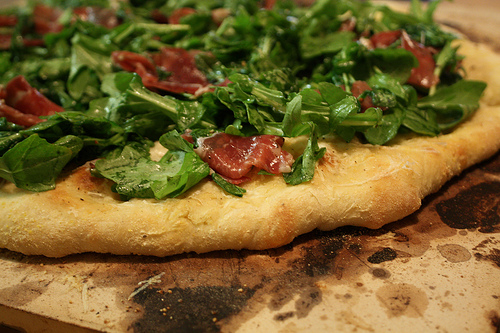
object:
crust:
[1, 41, 500, 259]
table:
[0, 155, 496, 333]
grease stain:
[375, 281, 429, 321]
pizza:
[0, 1, 499, 258]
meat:
[189, 131, 295, 185]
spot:
[128, 281, 262, 332]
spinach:
[0, 134, 69, 192]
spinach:
[92, 130, 213, 199]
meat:
[115, 46, 208, 94]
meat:
[0, 75, 66, 128]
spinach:
[365, 72, 480, 135]